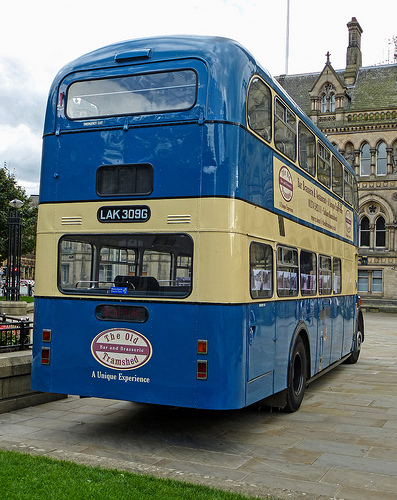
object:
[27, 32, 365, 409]
bus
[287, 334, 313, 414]
tire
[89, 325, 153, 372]
logo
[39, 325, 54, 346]
light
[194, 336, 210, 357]
light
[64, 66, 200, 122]
window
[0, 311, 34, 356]
fence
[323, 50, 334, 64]
cross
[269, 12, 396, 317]
building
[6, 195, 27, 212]
light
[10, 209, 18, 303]
pole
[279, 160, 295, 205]
logo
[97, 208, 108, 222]
letter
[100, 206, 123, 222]
letter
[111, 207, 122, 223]
letter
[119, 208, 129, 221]
number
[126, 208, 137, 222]
number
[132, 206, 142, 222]
number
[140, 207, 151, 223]
letter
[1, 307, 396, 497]
parking lot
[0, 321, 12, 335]
flower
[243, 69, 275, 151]
window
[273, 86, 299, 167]
window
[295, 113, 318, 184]
window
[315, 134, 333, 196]
window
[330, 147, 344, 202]
window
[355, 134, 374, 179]
window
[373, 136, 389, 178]
window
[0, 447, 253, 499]
grass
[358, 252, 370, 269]
mirror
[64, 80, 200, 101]
handrail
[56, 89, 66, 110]
handle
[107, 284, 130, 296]
sticker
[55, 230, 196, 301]
window